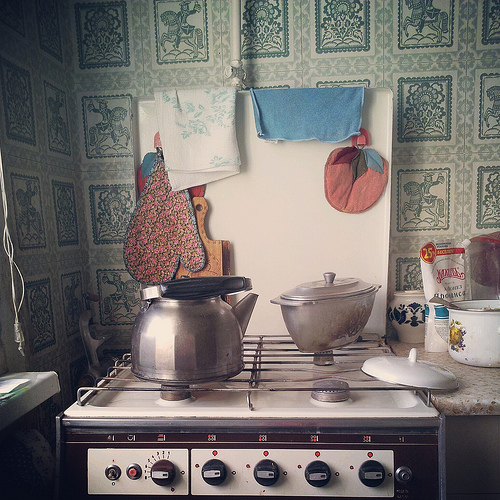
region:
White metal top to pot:
[353, 347, 462, 394]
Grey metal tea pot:
[129, 283, 261, 387]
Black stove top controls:
[87, 447, 399, 492]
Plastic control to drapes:
[1, 187, 35, 352]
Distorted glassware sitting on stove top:
[274, 252, 382, 358]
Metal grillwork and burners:
[73, 322, 433, 406]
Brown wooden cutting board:
[166, 193, 226, 277]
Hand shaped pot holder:
[120, 167, 207, 278]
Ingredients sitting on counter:
[418, 230, 478, 362]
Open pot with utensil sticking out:
[426, 291, 498, 369]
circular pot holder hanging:
[317, 124, 388, 228]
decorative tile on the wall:
[387, 85, 486, 237]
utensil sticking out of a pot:
[432, 296, 499, 356]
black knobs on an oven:
[193, 451, 393, 498]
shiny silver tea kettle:
[130, 266, 261, 391]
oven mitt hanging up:
[117, 150, 206, 286]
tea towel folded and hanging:
[152, 90, 246, 193]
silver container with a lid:
[267, 247, 383, 367]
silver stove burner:
[307, 372, 361, 411]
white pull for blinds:
[3, 238, 29, 363]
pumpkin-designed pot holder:
[321, 126, 389, 219]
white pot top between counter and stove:
[353, 344, 463, 396]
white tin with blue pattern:
[388, 284, 430, 346]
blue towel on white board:
[249, 83, 369, 148]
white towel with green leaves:
[151, 81, 246, 191]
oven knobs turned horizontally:
[146, 458, 389, 495]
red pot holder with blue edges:
[118, 150, 210, 287]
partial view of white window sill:
[0, 369, 64, 427]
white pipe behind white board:
[223, 0, 247, 88]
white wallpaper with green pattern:
[6, 26, 496, 421]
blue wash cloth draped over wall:
[250, 88, 365, 140]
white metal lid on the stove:
[359, 348, 456, 393]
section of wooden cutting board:
[168, 195, 225, 276]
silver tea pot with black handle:
[131, 274, 259, 384]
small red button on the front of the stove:
[128, 465, 135, 475]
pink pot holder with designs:
[323, 127, 388, 212]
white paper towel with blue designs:
[153, 88, 243, 188]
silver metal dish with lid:
[271, 273, 383, 348]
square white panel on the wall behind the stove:
[137, 91, 388, 335]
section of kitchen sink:
[1, 370, 59, 422]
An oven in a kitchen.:
[5, 7, 492, 492]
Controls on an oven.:
[63, 422, 438, 496]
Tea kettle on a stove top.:
[126, 269, 263, 394]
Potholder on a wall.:
[321, 125, 386, 214]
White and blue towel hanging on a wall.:
[145, 83, 248, 200]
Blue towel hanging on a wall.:
[243, 88, 370, 142]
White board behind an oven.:
[130, 98, 387, 345]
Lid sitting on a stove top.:
[364, 345, 464, 395]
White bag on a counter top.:
[415, 238, 468, 354]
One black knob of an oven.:
[190, 450, 240, 494]